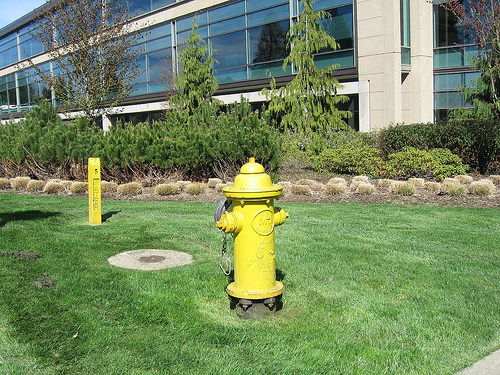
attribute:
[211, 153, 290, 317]
hydrant — yellow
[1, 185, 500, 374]
lawn — green, mowed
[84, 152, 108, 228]
pole — yellow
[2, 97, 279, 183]
shrubs — green, group, small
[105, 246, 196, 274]
cement — circle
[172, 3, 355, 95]
windows — glass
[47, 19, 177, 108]
windows — glass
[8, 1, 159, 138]
tree — red, tall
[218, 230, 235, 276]
chain — silver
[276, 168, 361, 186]
dirt — brown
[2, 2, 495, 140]
building — large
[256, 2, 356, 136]
tree — pine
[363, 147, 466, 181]
bushes — green, tall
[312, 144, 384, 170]
bushes — green, tall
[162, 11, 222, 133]
tree — evergreen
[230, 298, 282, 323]
base — gray